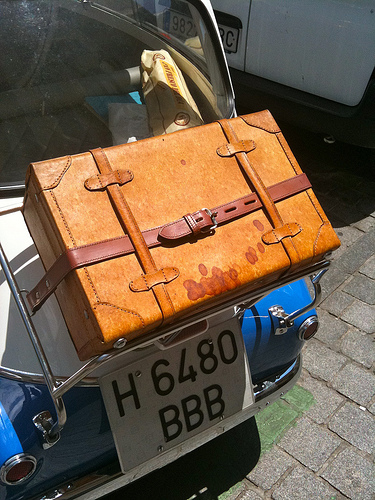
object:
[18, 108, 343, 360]
suitcase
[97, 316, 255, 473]
license plate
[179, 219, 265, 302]
stains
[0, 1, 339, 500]
blue car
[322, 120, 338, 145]
ground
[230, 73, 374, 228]
shadow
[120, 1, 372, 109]
car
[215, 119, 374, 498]
ground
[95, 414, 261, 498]
shadow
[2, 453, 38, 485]
lights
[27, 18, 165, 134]
floor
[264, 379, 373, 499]
floor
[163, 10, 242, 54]
license plate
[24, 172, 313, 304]
leather strap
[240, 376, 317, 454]
green spot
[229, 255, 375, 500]
ground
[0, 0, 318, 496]
rear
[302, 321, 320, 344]
light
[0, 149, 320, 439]
trunk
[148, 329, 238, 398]
numbers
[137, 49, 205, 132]
bag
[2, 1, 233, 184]
glass